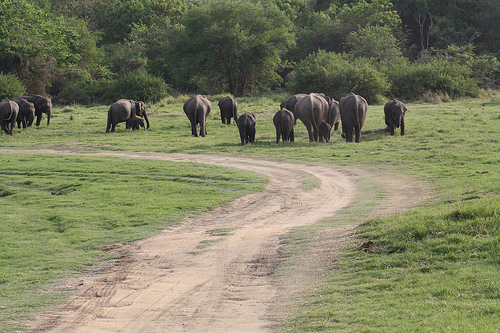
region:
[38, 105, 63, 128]
the trunk of a elephant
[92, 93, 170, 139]
a big grey elephant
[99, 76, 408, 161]
a lot of elephants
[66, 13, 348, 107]
a heavily bush in the distance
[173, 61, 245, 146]
a elephant standing on grass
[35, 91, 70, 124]
the head of a elephant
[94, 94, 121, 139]
the back end of a elephant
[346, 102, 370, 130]
the tail of a elephant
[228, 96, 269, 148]
a grey baby elephant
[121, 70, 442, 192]
elephants in a field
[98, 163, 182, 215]
this is the grass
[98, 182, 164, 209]
the grass is short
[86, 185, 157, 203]
the grass is green in color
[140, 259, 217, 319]
this is a path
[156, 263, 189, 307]
the path is sandy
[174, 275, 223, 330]
the sand is brown in color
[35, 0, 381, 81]
these are the trees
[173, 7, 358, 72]
the trees are short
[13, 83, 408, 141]
these are some elephants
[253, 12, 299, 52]
the leaves are green in color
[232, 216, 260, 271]
part of a ground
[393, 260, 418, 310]
part of a grass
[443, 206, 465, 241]
part of a grass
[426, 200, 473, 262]
part of a grass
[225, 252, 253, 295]
part of a ground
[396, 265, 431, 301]
part of a ground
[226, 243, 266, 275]
part of a track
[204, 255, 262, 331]
part of a ground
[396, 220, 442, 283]
part of a grass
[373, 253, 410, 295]
part of a grass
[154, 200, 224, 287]
edge of a road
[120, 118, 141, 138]
part of a young one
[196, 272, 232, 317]
part of a track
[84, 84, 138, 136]
This is an elephant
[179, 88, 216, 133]
This is an elephant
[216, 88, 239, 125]
This is an elephant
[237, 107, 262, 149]
This is an elephant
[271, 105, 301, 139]
This is an elephant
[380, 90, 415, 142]
This is an elephant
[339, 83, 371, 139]
This is an elephant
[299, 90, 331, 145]
This is an elephant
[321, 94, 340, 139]
This is an elephant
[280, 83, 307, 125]
This is an elephant